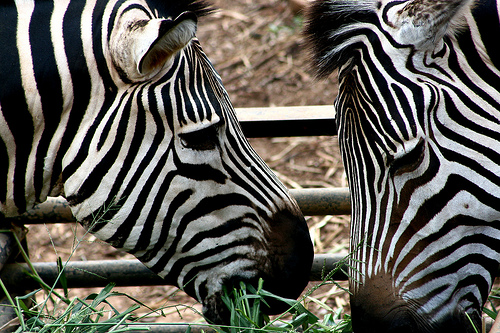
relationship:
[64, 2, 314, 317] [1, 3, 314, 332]
head of zebra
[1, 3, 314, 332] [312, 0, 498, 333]
zebra next to zebra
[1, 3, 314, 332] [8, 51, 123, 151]
zebra has stripes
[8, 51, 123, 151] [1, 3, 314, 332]
stripes on zebra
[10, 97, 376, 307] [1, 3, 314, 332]
fence behind zebra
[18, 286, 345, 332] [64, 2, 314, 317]
grass below head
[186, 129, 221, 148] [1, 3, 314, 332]
eye of zebra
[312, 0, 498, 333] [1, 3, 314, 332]
zebra next to zebra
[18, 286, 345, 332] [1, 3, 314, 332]
grass below zebra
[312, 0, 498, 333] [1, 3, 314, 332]
zebra facing or zebra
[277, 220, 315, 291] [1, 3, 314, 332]
nose of zebra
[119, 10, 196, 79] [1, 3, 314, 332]
ear of zebra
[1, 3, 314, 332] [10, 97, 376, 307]
zebra inside fence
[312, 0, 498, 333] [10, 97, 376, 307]
zebra inside fence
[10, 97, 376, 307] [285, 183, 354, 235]
fence has bars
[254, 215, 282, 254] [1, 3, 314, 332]
dirt on zebra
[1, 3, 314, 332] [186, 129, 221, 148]
zebra has eye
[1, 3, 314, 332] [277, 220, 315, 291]
zebra has a nose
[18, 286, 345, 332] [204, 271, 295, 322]
grass in mouth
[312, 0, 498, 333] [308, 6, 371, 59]
zebra has mane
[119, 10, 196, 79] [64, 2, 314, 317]
ear on head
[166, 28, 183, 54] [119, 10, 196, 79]
hair in ear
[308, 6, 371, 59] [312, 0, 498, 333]
mane on zebra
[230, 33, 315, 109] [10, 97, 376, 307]
dirt beyond fence